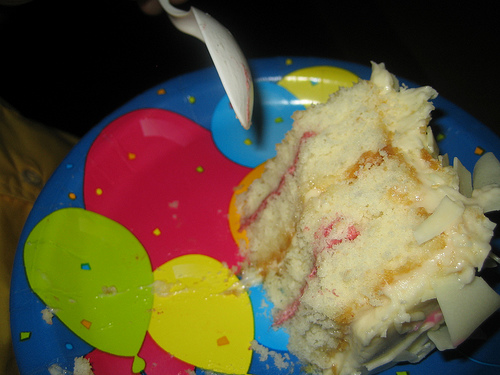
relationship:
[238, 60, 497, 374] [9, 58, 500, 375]
cake on plate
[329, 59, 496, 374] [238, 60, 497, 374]
frosting on cake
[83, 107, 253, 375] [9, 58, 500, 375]
pink on plate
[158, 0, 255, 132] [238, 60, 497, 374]
spoon near cake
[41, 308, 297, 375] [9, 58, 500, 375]
crumbs on plate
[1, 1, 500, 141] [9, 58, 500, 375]
dark area near plate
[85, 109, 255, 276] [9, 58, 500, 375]
balloon on plate